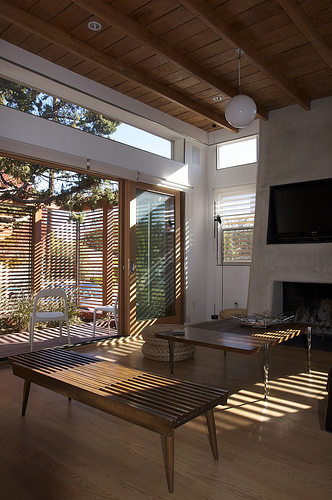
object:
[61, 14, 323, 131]
ceiling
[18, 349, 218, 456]
bench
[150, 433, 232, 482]
legs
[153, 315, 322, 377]
table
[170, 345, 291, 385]
legs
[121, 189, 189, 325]
door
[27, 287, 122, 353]
chairs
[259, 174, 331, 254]
tv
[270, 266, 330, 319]
fireplace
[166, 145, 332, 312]
wall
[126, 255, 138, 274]
handle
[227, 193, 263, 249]
blinds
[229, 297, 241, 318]
socket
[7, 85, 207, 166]
window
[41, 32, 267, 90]
beam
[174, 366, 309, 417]
shadow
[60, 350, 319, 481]
floor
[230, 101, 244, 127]
bulb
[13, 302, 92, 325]
grass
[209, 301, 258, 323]
basket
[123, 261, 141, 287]
lock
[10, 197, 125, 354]
patio